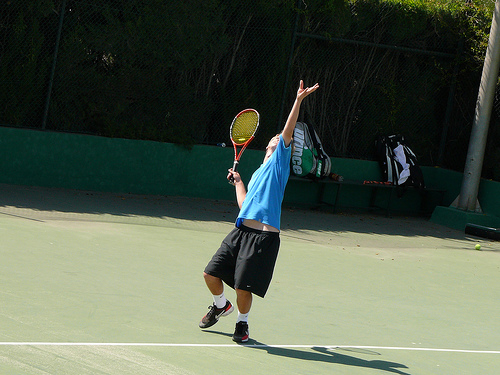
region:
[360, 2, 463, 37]
Leaves are green color.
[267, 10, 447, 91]
Trees are behind the fence.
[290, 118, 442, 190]
Two backpack are in bench.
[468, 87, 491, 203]
Pole is grey color.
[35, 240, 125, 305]
Ground is grey color.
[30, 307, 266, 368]
White lines in the ground.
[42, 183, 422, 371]
Shadow falls on ground.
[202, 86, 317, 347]
One man is playing tennis.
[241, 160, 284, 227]
Man is wearing blue shirt.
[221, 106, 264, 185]
Tennis racket is red and black.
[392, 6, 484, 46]
Leaves are green color.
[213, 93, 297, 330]
Man is playing tennis.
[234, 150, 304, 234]
Man is in blue shirt.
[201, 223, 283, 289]
Man is in black shorts.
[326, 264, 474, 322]
Ground is grey color.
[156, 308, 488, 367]
White lines are in ground.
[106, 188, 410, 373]
Shadow falls on the ground.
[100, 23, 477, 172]
Trees are behind the fence.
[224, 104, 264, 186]
Tennis racquet is red and black color.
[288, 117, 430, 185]
Two backpack are in the bench.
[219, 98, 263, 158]
Tennis racket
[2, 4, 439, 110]
Metal fence.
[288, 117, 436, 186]
Bags to hold tennis equipment.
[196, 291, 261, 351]
Tennis shoes and long socks.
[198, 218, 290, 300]
Black athletic shorts.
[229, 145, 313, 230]
Blue t shirt.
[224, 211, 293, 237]
Mans midriff.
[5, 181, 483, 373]
Tennis court.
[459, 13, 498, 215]
Large metal pole.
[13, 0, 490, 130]
Trees behind the metal fence.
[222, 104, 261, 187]
The racket held by the player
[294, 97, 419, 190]
The bags that are on the bench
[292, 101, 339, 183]
The larger of the two bags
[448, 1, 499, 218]
The silver pole in the court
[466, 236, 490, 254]
The ball in front of the silver pole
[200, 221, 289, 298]
The player's black shorts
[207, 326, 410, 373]
The shadow of the player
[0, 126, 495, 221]
The green wall behind the player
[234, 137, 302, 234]
The player's blue shirt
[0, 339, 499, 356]
The white line at the end of the court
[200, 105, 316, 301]
Person holding tennis racquet.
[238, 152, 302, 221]
Person wearing blue shirt.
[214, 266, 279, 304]
Person wearing black shorts.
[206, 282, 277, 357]
Person wearing white socks.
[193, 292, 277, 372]
Person wearing black, white, and red shoes.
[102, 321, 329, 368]
White line on court.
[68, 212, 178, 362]
Tennis court is green in color.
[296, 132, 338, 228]
Green bag near wall.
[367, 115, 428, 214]
Black and white bag near wall.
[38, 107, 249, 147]
Fence behind tennis player.